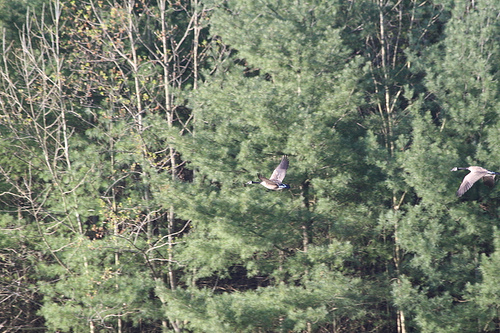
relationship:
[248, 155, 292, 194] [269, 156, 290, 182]
duck has wings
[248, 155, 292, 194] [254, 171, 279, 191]
duck has wings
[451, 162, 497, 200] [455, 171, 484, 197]
duck has wings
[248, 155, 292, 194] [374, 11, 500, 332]
duck flying by tree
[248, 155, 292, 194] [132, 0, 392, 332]
duck flying by tree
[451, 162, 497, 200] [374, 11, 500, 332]
duck flying by tree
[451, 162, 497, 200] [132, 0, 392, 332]
duck flying by tree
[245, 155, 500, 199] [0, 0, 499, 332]
ducks flying by trees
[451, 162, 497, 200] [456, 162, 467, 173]
duck has neck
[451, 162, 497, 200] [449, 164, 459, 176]
duck has face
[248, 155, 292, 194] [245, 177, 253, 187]
duck has face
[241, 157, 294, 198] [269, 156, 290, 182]
goose has wings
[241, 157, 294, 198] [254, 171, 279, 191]
goose has wings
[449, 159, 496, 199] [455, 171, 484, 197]
goose has wings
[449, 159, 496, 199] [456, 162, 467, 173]
goose has neck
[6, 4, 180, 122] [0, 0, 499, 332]
leaves on trees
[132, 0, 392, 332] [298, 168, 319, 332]
tree has truck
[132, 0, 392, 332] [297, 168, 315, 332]
tree has trunk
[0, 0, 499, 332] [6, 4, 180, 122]
trees has leaves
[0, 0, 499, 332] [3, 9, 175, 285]
trees has branches